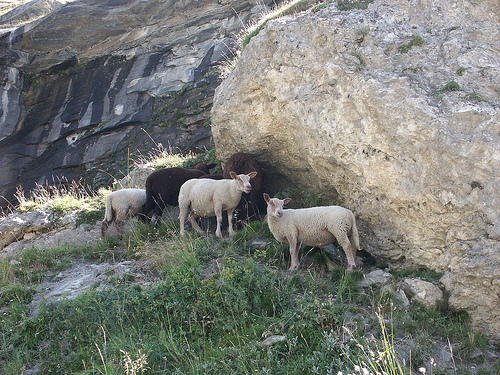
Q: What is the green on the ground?
A: Grass.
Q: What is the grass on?
A: Hill.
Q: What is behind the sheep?
A: Rock wall.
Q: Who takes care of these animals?
A: Shepherd.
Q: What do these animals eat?
A: Plants.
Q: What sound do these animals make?
A: Bleat.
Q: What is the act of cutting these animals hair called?
A: Shearing.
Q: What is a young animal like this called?
A: Lamb.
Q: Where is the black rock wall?
A: Background.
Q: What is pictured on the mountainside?
A: Sheep on the mountainside.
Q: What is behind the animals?
A: A rock formation.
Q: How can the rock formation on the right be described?
A: Light colored rock formation.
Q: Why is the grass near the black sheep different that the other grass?
A: Sunlight is beaming on the ground in those areas.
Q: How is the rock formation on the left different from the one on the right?
A: It is black.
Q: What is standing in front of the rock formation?
A: A group of sheep.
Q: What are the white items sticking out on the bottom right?
A: Some wild mountain flowers.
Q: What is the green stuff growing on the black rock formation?
A: Moss.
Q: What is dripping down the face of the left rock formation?
A: Water.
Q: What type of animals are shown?
A: Sheep.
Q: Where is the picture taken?
A: A mountainside.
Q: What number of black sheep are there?
A: One.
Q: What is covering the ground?
A: Grass.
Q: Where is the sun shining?
A: Rocks.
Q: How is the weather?
A: Sunny.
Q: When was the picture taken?
A: Afternoon.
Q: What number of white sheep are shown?
A: 3.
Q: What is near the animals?
A: Rock.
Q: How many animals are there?
A: 4.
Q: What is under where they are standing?
A: Grass.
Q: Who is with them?
A: No one.